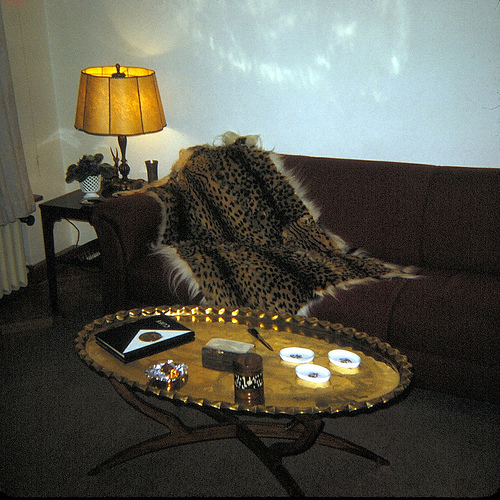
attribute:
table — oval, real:
[77, 306, 417, 419]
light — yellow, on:
[73, 65, 168, 192]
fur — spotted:
[137, 141, 414, 320]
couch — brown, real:
[89, 145, 493, 394]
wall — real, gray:
[47, 7, 499, 162]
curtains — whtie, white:
[0, 35, 39, 310]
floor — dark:
[0, 334, 66, 499]